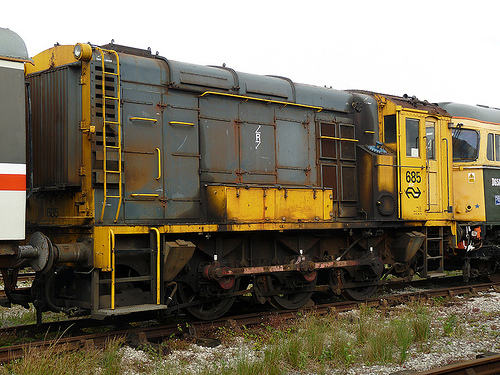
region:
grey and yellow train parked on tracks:
[29, 35, 498, 332]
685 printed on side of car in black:
[403, 167, 423, 184]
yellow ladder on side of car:
[97, 49, 126, 224]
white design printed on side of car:
[251, 116, 264, 153]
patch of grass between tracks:
[207, 317, 442, 369]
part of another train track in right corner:
[394, 347, 496, 374]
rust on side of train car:
[260, 187, 272, 224]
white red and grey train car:
[0, 25, 32, 244]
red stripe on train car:
[0, 167, 28, 194]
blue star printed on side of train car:
[474, 197, 481, 212]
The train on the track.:
[53, 58, 474, 268]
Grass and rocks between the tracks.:
[300, 300, 476, 352]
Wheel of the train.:
[175, 253, 248, 309]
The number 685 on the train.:
[396, 138, 434, 195]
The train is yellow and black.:
[79, 103, 486, 233]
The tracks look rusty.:
[5, 302, 285, 374]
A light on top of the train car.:
[63, 41, 97, 65]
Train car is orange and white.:
[4, 156, 30, 232]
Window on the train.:
[456, 119, 488, 173]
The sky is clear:
[191, 0, 478, 75]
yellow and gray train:
[26, 49, 495, 266]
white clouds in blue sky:
[218, 24, 275, 55]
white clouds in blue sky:
[396, 41, 448, 74]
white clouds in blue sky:
[328, 30, 377, 82]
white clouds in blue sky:
[313, 25, 343, 55]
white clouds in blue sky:
[351, 43, 374, 74]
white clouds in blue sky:
[255, 14, 321, 83]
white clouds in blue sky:
[405, 2, 433, 59]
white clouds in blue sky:
[358, 25, 419, 69]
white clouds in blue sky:
[312, 19, 386, 88]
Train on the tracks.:
[1, 26, 496, 325]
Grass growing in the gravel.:
[2, 299, 482, 374]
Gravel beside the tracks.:
[75, 285, 497, 372]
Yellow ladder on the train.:
[90, 35, 127, 222]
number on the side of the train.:
[402, 165, 426, 185]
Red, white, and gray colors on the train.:
[0, 24, 30, 252]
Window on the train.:
[401, 113, 423, 160]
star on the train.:
[473, 200, 479, 212]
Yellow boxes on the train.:
[207, 174, 337, 226]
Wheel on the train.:
[254, 256, 324, 314]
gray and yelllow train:
[29, 44, 497, 299]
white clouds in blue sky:
[170, 11, 219, 45]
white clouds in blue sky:
[394, 41, 470, 98]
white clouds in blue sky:
[318, 25, 367, 63]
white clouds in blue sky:
[342, 0, 434, 69]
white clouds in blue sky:
[372, 11, 467, 49]